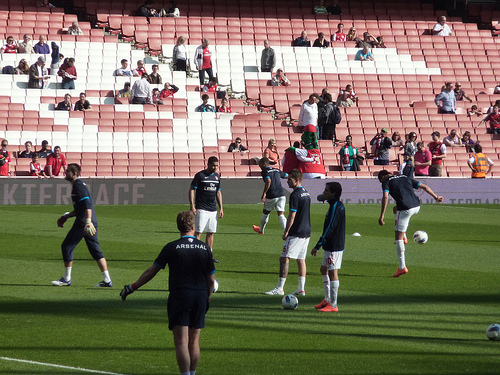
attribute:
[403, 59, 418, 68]
seat — red 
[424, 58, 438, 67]
seat — red 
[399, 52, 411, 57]
seat — red 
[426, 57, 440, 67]
seat — red 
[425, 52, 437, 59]
seat — red 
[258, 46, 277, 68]
jacket — dark 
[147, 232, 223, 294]
shirt — blue 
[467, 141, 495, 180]
person — waiting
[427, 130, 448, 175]
person — waiting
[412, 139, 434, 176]
person — waiting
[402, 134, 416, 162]
person — waiting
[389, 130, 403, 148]
person — waiting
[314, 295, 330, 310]
shoe — orange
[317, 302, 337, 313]
shoe — orange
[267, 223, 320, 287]
shorts — white 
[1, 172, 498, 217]
wall — grey 